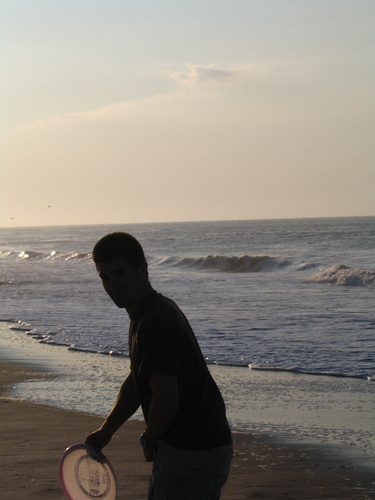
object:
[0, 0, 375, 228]
sky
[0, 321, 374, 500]
shore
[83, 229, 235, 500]
man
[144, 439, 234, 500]
shorts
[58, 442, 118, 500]
frisbee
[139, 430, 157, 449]
watch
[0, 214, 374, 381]
ocean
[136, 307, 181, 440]
arm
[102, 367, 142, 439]
arm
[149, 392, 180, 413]
elbow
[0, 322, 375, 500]
beach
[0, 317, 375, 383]
waves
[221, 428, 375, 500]
sand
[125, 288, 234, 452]
shirt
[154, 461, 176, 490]
pocket